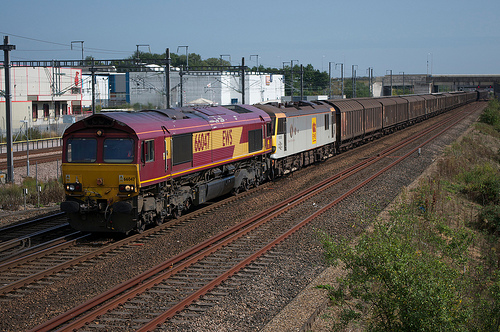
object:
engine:
[59, 104, 276, 233]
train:
[54, 84, 495, 235]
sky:
[196, 0, 497, 47]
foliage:
[395, 178, 421, 206]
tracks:
[220, 196, 309, 266]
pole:
[0, 34, 18, 185]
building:
[1, 67, 63, 141]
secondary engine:
[251, 99, 342, 179]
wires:
[17, 37, 137, 55]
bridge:
[433, 74, 497, 86]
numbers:
[193, 133, 198, 152]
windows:
[64, 136, 99, 163]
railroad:
[77, 252, 237, 330]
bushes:
[3, 182, 24, 210]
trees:
[285, 62, 327, 94]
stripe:
[174, 123, 211, 131]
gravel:
[109, 255, 136, 274]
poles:
[163, 46, 174, 108]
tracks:
[0, 238, 91, 290]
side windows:
[140, 137, 158, 166]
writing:
[218, 129, 237, 147]